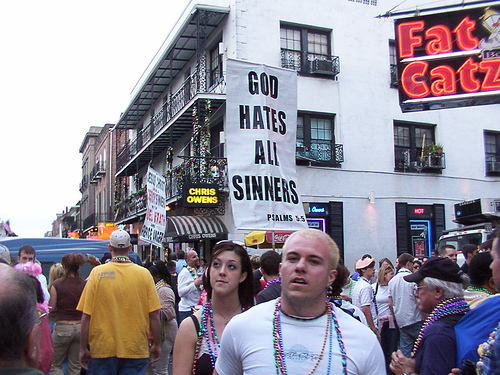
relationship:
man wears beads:
[208, 226, 390, 374] [269, 291, 353, 374]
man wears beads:
[388, 251, 472, 371] [409, 294, 469, 364]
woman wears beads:
[170, 237, 263, 374] [190, 299, 251, 374]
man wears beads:
[71, 226, 166, 374] [105, 253, 133, 266]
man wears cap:
[71, 226, 166, 374] [108, 226, 133, 251]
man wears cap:
[388, 251, 472, 371] [397, 253, 471, 285]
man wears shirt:
[71, 226, 166, 374] [73, 259, 166, 364]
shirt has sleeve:
[73, 259, 166, 364] [76, 264, 100, 318]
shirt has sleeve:
[73, 259, 166, 364] [144, 274, 164, 319]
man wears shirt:
[208, 226, 390, 374] [210, 296, 388, 374]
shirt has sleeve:
[210, 296, 388, 374] [212, 317, 245, 375]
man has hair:
[208, 226, 390, 374] [277, 227, 344, 273]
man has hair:
[388, 251, 472, 371] [418, 275, 465, 303]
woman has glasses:
[170, 237, 263, 374] [209, 235, 247, 254]